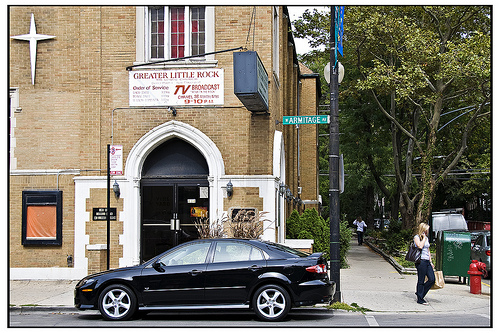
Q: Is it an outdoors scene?
A: Yes, it is outdoors.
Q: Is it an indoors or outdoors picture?
A: It is outdoors.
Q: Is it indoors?
A: No, it is outdoors.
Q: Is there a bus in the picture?
A: No, there are no buses.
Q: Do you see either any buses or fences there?
A: No, there are no buses or fences.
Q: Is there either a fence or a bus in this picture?
A: No, there are no buses or fences.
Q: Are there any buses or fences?
A: No, there are no buses or fences.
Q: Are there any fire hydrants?
A: Yes, there is a fire hydrant.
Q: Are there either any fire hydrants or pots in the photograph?
A: Yes, there is a fire hydrant.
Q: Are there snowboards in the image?
A: No, there are no snowboards.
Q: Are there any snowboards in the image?
A: No, there are no snowboards.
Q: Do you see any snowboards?
A: No, there are no snowboards.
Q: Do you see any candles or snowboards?
A: No, there are no snowboards or candles.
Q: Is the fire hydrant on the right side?
A: Yes, the fire hydrant is on the right of the image.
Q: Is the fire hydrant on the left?
A: No, the fire hydrant is on the right of the image.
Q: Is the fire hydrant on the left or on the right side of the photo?
A: The fire hydrant is on the right of the image.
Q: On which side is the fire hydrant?
A: The fire hydrant is on the right of the image.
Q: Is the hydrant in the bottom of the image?
A: Yes, the hydrant is in the bottom of the image.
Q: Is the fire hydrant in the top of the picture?
A: No, the fire hydrant is in the bottom of the image.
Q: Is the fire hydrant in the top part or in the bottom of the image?
A: The fire hydrant is in the bottom of the image.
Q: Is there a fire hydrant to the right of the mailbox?
A: Yes, there is a fire hydrant to the right of the mailbox.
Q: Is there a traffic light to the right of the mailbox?
A: No, there is a fire hydrant to the right of the mailbox.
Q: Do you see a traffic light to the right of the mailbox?
A: No, there is a fire hydrant to the right of the mailbox.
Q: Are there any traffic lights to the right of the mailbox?
A: No, there is a fire hydrant to the right of the mailbox.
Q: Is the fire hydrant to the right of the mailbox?
A: Yes, the fire hydrant is to the right of the mailbox.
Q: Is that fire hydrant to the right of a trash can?
A: No, the fire hydrant is to the right of the mailbox.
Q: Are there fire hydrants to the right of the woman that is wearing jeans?
A: Yes, there is a fire hydrant to the right of the woman.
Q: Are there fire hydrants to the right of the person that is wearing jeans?
A: Yes, there is a fire hydrant to the right of the woman.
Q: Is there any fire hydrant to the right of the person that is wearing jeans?
A: Yes, there is a fire hydrant to the right of the woman.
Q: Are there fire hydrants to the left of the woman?
A: No, the fire hydrant is to the right of the woman.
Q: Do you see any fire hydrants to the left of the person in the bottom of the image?
A: No, the fire hydrant is to the right of the woman.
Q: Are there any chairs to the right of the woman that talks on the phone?
A: No, there is a fire hydrant to the right of the woman.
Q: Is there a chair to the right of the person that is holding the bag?
A: No, there is a fire hydrant to the right of the woman.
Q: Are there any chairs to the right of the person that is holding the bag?
A: No, there is a fire hydrant to the right of the woman.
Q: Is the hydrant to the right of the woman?
A: Yes, the hydrant is to the right of the woman.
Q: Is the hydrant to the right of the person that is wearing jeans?
A: Yes, the hydrant is to the right of the woman.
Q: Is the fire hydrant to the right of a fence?
A: No, the fire hydrant is to the right of the woman.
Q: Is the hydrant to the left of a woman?
A: No, the hydrant is to the right of a woman.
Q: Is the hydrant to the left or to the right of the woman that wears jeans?
A: The hydrant is to the right of the woman.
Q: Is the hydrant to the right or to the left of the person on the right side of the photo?
A: The hydrant is to the right of the woman.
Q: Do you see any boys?
A: No, there are no boys.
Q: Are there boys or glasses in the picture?
A: No, there are no boys or glasses.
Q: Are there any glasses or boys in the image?
A: No, there are no boys or glasses.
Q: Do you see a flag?
A: No, there are no flags.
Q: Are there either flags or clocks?
A: No, there are no flags or clocks.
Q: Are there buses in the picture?
A: No, there are no buses.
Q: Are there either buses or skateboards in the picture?
A: No, there are no buses or skateboards.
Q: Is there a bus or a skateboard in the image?
A: No, there are no buses or skateboards.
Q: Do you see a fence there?
A: No, there are no fences.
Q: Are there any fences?
A: No, there are no fences.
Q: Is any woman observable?
A: Yes, there is a woman.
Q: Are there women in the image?
A: Yes, there is a woman.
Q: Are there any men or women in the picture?
A: Yes, there is a woman.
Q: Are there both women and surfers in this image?
A: No, there is a woman but no surfers.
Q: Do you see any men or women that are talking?
A: Yes, the woman is talking.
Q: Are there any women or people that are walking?
A: Yes, the woman is walking.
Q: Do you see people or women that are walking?
A: Yes, the woman is walking.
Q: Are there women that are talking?
A: Yes, there is a woman that is talking.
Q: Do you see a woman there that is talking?
A: Yes, there is a woman that is talking.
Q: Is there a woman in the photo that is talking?
A: Yes, there is a woman that is talking.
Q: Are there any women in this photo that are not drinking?
A: Yes, there is a woman that is talking.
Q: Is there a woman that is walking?
A: Yes, there is a woman that is walking.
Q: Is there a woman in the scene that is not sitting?
A: Yes, there is a woman that is walking.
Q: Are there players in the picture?
A: No, there are no players.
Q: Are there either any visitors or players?
A: No, there are no players or visitors.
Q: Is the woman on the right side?
A: Yes, the woman is on the right of the image.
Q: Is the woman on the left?
A: No, the woman is on the right of the image.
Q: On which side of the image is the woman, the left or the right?
A: The woman is on the right of the image.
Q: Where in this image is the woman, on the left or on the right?
A: The woman is on the right of the image.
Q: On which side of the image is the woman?
A: The woman is on the right of the image.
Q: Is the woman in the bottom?
A: Yes, the woman is in the bottom of the image.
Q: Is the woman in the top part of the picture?
A: No, the woman is in the bottom of the image.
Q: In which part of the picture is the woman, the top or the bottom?
A: The woman is in the bottom of the image.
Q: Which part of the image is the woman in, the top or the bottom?
A: The woman is in the bottom of the image.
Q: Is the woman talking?
A: Yes, the woman is talking.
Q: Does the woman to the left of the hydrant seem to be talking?
A: Yes, the woman is talking.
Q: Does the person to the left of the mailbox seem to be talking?
A: Yes, the woman is talking.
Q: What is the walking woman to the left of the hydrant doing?
A: The woman is talking.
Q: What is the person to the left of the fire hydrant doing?
A: The woman is talking.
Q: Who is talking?
A: The woman is talking.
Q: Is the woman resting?
A: No, the woman is talking.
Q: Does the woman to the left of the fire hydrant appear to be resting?
A: No, the woman is talking.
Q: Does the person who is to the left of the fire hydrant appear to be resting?
A: No, the woman is talking.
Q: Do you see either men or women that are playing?
A: No, there is a woman but she is talking.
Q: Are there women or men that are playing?
A: No, there is a woman but she is talking.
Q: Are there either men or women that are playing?
A: No, there is a woman but she is talking.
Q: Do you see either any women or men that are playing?
A: No, there is a woman but she is talking.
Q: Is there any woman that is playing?
A: No, there is a woman but she is talking.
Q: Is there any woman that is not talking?
A: No, there is a woman but she is talking.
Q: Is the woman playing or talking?
A: The woman is talking.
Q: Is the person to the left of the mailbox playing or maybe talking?
A: The woman is talking.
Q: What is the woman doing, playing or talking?
A: The woman is talking.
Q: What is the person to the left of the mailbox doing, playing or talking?
A: The woman is talking.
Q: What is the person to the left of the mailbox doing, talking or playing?
A: The woman is talking.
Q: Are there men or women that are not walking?
A: No, there is a woman but she is walking.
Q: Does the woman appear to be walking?
A: Yes, the woman is walking.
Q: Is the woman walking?
A: Yes, the woman is walking.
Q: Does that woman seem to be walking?
A: Yes, the woman is walking.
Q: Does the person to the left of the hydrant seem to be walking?
A: Yes, the woman is walking.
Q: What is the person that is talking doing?
A: The woman is walking.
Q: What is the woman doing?
A: The woman is walking.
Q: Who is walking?
A: The woman is walking.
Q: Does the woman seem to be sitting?
A: No, the woman is walking.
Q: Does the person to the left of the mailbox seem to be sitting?
A: No, the woman is walking.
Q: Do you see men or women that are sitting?
A: No, there is a woman but she is walking.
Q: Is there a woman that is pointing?
A: No, there is a woman but she is walking.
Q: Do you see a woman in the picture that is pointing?
A: No, there is a woman but she is walking.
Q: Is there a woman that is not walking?
A: No, there is a woman but she is walking.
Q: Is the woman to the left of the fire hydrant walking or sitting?
A: The woman is walking.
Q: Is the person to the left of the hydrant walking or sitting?
A: The woman is walking.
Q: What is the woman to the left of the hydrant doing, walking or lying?
A: The woman is walking.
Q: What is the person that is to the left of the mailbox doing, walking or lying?
A: The woman is walking.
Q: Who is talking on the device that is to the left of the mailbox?
A: The woman is talking on the phone.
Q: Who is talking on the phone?
A: The woman is talking on the phone.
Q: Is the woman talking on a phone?
A: Yes, the woman is talking on a phone.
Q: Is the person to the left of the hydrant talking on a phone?
A: Yes, the woman is talking on a phone.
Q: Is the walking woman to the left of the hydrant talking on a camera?
A: No, the woman is talking on a phone.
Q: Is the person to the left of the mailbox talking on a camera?
A: No, the woman is talking on a phone.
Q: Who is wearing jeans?
A: The woman is wearing jeans.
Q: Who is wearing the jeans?
A: The woman is wearing jeans.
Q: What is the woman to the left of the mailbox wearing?
A: The woman is wearing jeans.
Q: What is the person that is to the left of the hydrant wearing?
A: The woman is wearing jeans.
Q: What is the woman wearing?
A: The woman is wearing jeans.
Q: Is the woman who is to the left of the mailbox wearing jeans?
A: Yes, the woman is wearing jeans.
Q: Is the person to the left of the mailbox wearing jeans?
A: Yes, the woman is wearing jeans.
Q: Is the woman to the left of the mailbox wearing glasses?
A: No, the woman is wearing jeans.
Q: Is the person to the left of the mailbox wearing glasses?
A: No, the woman is wearing jeans.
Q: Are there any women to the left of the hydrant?
A: Yes, there is a woman to the left of the hydrant.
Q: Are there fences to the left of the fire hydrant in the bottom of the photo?
A: No, there is a woman to the left of the fire hydrant.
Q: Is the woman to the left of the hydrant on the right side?
A: Yes, the woman is to the left of the hydrant.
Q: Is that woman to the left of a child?
A: No, the woman is to the left of the hydrant.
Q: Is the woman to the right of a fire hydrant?
A: No, the woman is to the left of a fire hydrant.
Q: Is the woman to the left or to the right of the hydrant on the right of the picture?
A: The woman is to the left of the hydrant.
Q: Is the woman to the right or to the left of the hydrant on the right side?
A: The woman is to the left of the hydrant.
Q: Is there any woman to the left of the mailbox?
A: Yes, there is a woman to the left of the mailbox.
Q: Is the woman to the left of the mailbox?
A: Yes, the woman is to the left of the mailbox.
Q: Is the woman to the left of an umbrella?
A: No, the woman is to the left of the mailbox.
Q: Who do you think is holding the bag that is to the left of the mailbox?
A: The woman is holding the bag.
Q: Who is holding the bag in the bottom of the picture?
A: The woman is holding the bag.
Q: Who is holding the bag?
A: The woman is holding the bag.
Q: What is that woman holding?
A: The woman is holding the bag.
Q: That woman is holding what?
A: The woman is holding the bag.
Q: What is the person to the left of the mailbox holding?
A: The woman is holding the bag.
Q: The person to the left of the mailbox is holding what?
A: The woman is holding the bag.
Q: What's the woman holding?
A: The woman is holding the bag.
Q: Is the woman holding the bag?
A: Yes, the woman is holding the bag.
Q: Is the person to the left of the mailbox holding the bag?
A: Yes, the woman is holding the bag.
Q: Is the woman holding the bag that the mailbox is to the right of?
A: Yes, the woman is holding the bag.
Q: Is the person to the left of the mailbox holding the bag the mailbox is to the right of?
A: Yes, the woman is holding the bag.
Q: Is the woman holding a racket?
A: No, the woman is holding the bag.